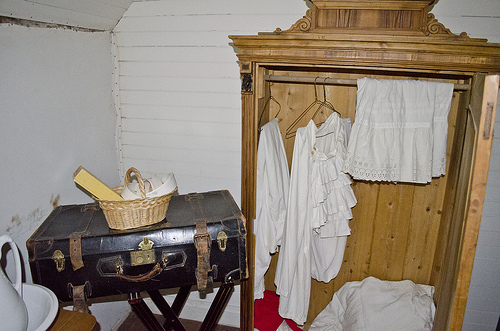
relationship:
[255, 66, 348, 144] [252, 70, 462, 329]
hanger holding clothing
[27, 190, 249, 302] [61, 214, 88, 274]
suitcase with strap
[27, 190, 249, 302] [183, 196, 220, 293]
suitcase with strap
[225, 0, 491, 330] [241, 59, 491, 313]
closet with open door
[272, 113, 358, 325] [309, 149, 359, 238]
shirt with lace trim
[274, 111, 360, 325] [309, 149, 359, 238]
clothes item with lace trim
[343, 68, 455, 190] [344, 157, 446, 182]
cloth with lace trim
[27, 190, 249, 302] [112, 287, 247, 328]
suitcase on stand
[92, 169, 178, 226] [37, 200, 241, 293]
basket on suitcase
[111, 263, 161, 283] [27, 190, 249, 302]
handle on suitcase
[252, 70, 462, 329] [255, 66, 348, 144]
clothing on hanger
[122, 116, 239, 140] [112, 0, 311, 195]
board on wall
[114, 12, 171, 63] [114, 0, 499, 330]
board on brick wall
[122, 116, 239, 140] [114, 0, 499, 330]
board on brick wall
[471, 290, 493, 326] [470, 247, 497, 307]
board on wall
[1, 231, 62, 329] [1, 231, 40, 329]
basin and basin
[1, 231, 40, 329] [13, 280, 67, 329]
basin and bowl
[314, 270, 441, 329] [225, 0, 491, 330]
blanket in bottom of closet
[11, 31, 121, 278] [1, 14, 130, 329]
fabric tacked to wall